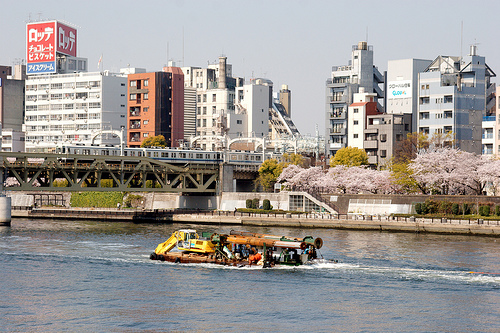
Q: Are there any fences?
A: No, there are no fences.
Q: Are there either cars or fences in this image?
A: No, there are no fences or cars.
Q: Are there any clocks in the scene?
A: No, there are no clocks.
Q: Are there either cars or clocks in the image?
A: No, there are no clocks or cars.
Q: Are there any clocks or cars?
A: No, there are no clocks or cars.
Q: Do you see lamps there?
A: No, there are no lamps.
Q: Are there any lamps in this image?
A: No, there are no lamps.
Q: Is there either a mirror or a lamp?
A: No, there are no lamps or mirrors.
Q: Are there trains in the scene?
A: Yes, there is a train.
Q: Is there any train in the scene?
A: Yes, there is a train.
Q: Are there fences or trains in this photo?
A: Yes, there is a train.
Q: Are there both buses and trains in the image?
A: No, there is a train but no buses.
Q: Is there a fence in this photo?
A: No, there are no fences.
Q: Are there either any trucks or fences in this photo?
A: No, there are no fences or trucks.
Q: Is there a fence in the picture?
A: No, there are no fences.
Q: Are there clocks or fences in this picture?
A: No, there are no fences or clocks.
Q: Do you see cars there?
A: No, there are no cars.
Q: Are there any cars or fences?
A: No, there are no cars or fences.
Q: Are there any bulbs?
A: No, there are no bulbs.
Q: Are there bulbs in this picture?
A: No, there are no bulbs.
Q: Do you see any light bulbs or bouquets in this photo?
A: No, there are no light bulbs or bouquets.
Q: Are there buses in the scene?
A: No, there are no buses.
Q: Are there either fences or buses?
A: No, there are no buses or fences.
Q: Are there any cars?
A: No, there are no cars.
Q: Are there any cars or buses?
A: No, there are no cars or buses.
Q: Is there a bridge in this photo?
A: Yes, there is a bridge.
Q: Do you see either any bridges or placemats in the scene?
A: Yes, there is a bridge.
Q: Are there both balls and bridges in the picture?
A: No, there is a bridge but no balls.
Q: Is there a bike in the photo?
A: No, there are no bikes.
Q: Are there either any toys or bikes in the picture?
A: No, there are no bikes or toys.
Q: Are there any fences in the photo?
A: No, there are no fences.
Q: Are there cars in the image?
A: No, there are no cars.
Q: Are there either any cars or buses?
A: No, there are no cars or buses.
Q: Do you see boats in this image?
A: Yes, there is a boat.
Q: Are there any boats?
A: Yes, there is a boat.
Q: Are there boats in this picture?
A: Yes, there is a boat.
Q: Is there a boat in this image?
A: Yes, there is a boat.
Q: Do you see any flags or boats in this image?
A: Yes, there is a boat.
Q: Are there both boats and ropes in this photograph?
A: No, there is a boat but no ropes.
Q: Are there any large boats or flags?
A: Yes, there is a large boat.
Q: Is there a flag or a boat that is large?
A: Yes, the boat is large.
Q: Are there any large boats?
A: Yes, there is a large boat.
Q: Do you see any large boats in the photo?
A: Yes, there is a large boat.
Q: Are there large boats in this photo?
A: Yes, there is a large boat.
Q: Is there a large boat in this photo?
A: Yes, there is a large boat.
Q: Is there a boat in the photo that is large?
A: Yes, there is a boat that is large.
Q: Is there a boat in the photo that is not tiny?
A: Yes, there is a large boat.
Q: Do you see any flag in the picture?
A: No, there are no flags.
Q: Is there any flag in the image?
A: No, there are no flags.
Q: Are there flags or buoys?
A: No, there are no flags or buoys.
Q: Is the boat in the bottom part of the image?
A: Yes, the boat is in the bottom of the image.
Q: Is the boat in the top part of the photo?
A: No, the boat is in the bottom of the image.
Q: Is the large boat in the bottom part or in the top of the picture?
A: The boat is in the bottom of the image.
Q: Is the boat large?
A: Yes, the boat is large.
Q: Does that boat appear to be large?
A: Yes, the boat is large.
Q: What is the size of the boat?
A: The boat is large.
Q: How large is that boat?
A: The boat is large.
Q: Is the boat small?
A: No, the boat is large.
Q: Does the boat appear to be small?
A: No, the boat is large.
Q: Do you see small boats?
A: No, there is a boat but it is large.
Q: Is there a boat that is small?
A: No, there is a boat but it is large.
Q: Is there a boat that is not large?
A: No, there is a boat but it is large.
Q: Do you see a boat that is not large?
A: No, there is a boat but it is large.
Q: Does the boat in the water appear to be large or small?
A: The boat is large.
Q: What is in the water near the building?
A: The boat is in the water.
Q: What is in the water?
A: The boat is in the water.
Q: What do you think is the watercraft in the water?
A: The watercraft is a boat.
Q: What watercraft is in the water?
A: The watercraft is a boat.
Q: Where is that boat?
A: The boat is in the water.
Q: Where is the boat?
A: The boat is in the water.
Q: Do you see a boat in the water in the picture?
A: Yes, there is a boat in the water.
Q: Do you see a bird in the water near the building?
A: No, there is a boat in the water.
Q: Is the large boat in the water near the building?
A: Yes, the boat is in the water.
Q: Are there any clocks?
A: No, there are no clocks.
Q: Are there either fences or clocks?
A: No, there are no clocks or fences.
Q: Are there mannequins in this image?
A: No, there are no mannequins.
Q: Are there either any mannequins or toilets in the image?
A: No, there are no mannequins or toilets.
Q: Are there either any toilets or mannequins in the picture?
A: No, there are no mannequins or toilets.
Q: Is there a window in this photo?
A: Yes, there is a window.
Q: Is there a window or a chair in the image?
A: Yes, there is a window.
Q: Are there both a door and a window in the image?
A: No, there is a window but no doors.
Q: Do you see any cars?
A: No, there are no cars.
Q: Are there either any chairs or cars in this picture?
A: No, there are no cars or chairs.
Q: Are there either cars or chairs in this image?
A: No, there are no cars or chairs.